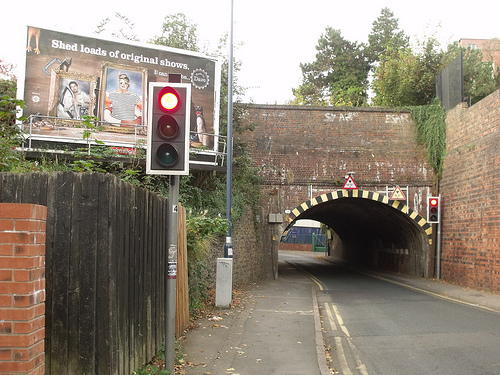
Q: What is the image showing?
A: It is showing a street.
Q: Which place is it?
A: It is a street.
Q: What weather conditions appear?
A: It is overcast.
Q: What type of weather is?
A: It is overcast.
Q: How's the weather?
A: It is overcast.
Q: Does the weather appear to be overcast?
A: Yes, it is overcast.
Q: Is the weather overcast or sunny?
A: It is overcast.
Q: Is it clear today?
A: No, it is overcast.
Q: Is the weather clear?
A: No, it is overcast.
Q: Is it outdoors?
A: Yes, it is outdoors.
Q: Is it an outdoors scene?
A: Yes, it is outdoors.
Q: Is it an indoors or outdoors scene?
A: It is outdoors.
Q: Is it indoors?
A: No, it is outdoors.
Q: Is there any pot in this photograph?
A: No, there are no pots.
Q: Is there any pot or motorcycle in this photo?
A: No, there are no pots or motorcycles.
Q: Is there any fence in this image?
A: Yes, there is a fence.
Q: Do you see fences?
A: Yes, there is a fence.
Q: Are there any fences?
A: Yes, there is a fence.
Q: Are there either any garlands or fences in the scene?
A: Yes, there is a fence.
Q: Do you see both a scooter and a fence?
A: No, there is a fence but no scooters.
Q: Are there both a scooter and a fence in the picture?
A: No, there is a fence but no scooters.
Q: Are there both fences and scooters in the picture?
A: No, there is a fence but no scooters.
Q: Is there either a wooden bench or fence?
A: Yes, there is a wood fence.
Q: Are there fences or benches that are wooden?
A: Yes, the fence is wooden.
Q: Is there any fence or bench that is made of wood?
A: Yes, the fence is made of wood.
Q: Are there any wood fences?
A: Yes, there is a fence that is made of wood.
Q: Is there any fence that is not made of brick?
A: Yes, there is a fence that is made of wood.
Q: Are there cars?
A: No, there are no cars.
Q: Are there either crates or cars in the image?
A: No, there are no cars or crates.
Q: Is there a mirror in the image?
A: No, there are no mirrors.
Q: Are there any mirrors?
A: No, there are no mirrors.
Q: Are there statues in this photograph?
A: No, there are no statues.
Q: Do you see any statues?
A: No, there are no statues.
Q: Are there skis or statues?
A: No, there are no statues or skis.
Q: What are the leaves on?
A: The leaves are on the tree.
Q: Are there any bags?
A: No, there are no bags.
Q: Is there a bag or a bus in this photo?
A: No, there are no bags or buses.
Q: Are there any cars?
A: No, there are no cars.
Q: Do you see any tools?
A: No, there are no tools.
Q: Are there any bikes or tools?
A: No, there are no tools or bikes.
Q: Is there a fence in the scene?
A: Yes, there is a fence.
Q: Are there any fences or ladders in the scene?
A: Yes, there is a fence.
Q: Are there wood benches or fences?
A: Yes, there is a wood fence.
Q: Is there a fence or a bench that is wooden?
A: Yes, the fence is wooden.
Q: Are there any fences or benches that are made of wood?
A: Yes, the fence is made of wood.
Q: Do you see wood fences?
A: Yes, there is a wood fence.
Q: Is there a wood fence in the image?
A: Yes, there is a wood fence.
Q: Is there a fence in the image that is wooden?
A: Yes, there is a fence that is wooden.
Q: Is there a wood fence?
A: Yes, there is a fence that is made of wood.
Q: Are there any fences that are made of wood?
A: Yes, there is a fence that is made of wood.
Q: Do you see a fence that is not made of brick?
A: Yes, there is a fence that is made of wood.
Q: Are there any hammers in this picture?
A: No, there are no hammers.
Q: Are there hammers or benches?
A: No, there are no hammers or benches.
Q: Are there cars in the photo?
A: No, there are no cars.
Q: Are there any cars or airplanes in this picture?
A: No, there are no cars or airplanes.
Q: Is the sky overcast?
A: Yes, the sky is overcast.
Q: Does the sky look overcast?
A: Yes, the sky is overcast.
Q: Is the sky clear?
A: No, the sky is overcast.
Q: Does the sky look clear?
A: No, the sky is overcast.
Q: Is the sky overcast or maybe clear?
A: The sky is overcast.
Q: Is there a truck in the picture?
A: No, there are no trucks.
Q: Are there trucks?
A: No, there are no trucks.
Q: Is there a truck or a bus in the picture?
A: No, there are no trucks or buses.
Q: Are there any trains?
A: No, there are no trains.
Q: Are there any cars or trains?
A: No, there are no trains or cars.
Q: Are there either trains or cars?
A: No, there are no trains or cars.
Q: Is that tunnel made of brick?
A: Yes, the tunnel is made of brick.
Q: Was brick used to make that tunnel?
A: Yes, the tunnel is made of brick.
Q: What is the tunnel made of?
A: The tunnel is made of brick.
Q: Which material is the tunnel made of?
A: The tunnel is made of brick.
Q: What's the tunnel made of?
A: The tunnel is made of brick.